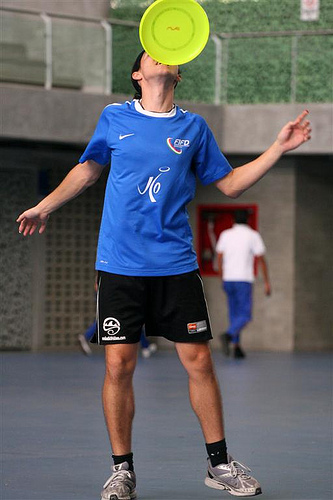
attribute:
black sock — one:
[206, 439, 228, 464]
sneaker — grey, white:
[202, 457, 258, 496]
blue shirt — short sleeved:
[92, 101, 225, 274]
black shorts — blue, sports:
[92, 268, 211, 346]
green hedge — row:
[115, 1, 332, 101]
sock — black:
[202, 431, 226, 470]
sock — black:
[109, 451, 136, 471]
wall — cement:
[2, 82, 332, 155]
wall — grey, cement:
[2, 84, 331, 352]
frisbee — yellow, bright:
[137, 1, 210, 69]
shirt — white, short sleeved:
[214, 220, 267, 282]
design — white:
[128, 159, 175, 207]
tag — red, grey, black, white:
[185, 318, 209, 335]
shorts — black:
[90, 263, 211, 345]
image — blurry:
[202, 200, 283, 364]